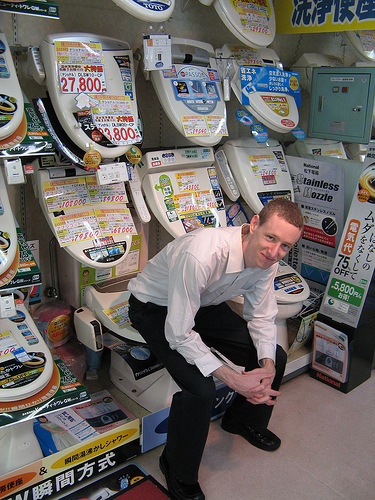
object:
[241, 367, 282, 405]
hands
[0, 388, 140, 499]
box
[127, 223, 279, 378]
shirt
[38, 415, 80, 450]
lady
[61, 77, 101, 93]
number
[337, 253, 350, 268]
number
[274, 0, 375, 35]
sign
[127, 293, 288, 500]
black pants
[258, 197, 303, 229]
red hair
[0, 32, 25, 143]
toilet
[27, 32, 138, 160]
toilet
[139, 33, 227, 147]
toilet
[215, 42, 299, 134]
toilet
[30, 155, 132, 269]
toilet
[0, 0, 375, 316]
wall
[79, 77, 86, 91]
number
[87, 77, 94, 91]
number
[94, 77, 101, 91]
number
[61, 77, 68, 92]
number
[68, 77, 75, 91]
number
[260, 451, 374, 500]
floor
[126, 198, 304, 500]
boy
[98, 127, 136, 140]
number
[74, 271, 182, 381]
toilet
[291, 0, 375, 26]
lettering